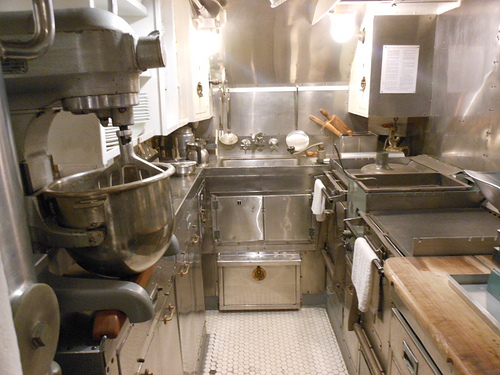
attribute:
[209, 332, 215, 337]
tile — white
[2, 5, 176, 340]
mixer — large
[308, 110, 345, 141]
rolling pin — wood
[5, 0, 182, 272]
mixer — professional, silver, metal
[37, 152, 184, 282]
bowl — silver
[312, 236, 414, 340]
towel — white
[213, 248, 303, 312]
box — steel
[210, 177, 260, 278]
door — silver, metal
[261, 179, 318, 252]
door — silver, metal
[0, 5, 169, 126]
mixer stand — stainless steel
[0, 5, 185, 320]
stand mixer — silver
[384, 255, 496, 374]
counter top — wood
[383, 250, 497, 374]
counter — light wood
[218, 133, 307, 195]
sink — stainless steel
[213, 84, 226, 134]
utensils — hanging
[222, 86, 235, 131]
utensils — hanging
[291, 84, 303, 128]
utensils — hanging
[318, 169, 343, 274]
oven — stainless, steel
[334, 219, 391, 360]
oven — stainless, steel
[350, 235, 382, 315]
towel — white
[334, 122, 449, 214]
bowl — silver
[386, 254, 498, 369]
countertop — wooden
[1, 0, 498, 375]
kitchen — professional